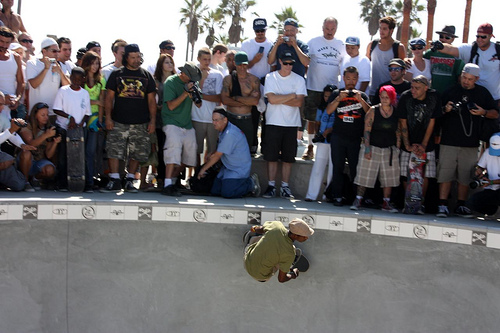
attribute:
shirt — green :
[242, 219, 296, 287]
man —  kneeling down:
[196, 105, 256, 200]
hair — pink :
[380, 83, 402, 103]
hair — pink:
[373, 84, 400, 102]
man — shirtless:
[219, 55, 260, 169]